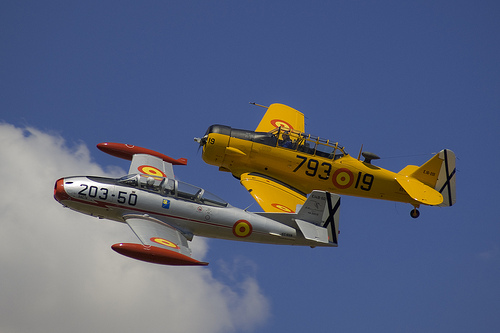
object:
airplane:
[53, 141, 339, 267]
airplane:
[190, 102, 457, 219]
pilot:
[144, 175, 155, 191]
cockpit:
[116, 173, 226, 208]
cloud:
[0, 118, 271, 332]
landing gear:
[409, 209, 419, 219]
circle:
[231, 220, 252, 239]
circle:
[329, 167, 357, 189]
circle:
[137, 163, 166, 181]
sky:
[0, 0, 499, 333]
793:
[291, 154, 333, 181]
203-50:
[77, 182, 138, 205]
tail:
[297, 189, 342, 250]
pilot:
[280, 130, 293, 152]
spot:
[322, 190, 339, 245]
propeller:
[193, 130, 209, 152]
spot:
[439, 147, 452, 208]